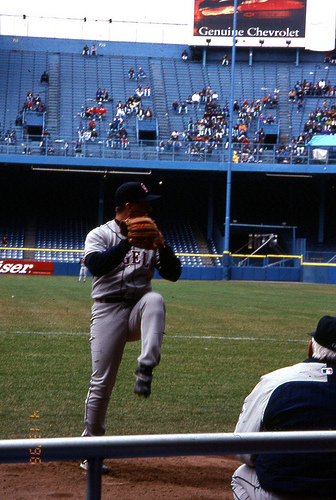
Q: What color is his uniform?
A: Grey.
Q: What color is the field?
A: Green and brown.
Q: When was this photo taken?
A: During the day.